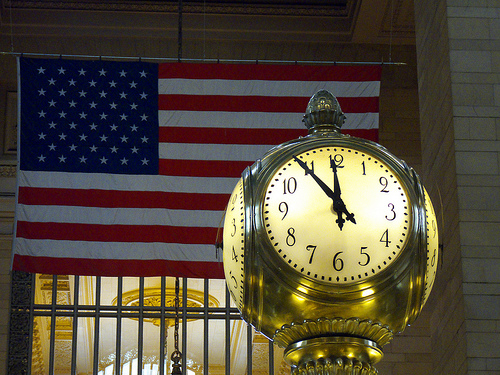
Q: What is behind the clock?
A: A flag.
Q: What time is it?
A: Almost 12.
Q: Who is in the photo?
A: No one.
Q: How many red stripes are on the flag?
A: Seven.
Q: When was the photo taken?
A: During the day.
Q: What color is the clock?
A: Gold.